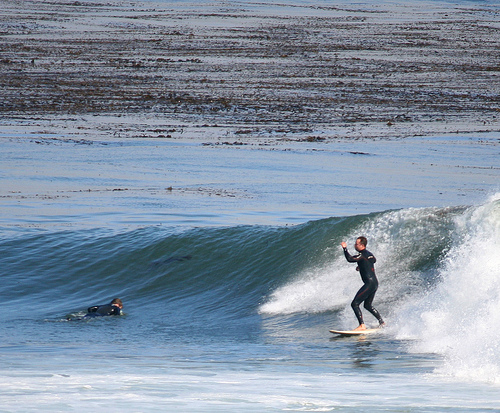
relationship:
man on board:
[341, 234, 388, 331] [304, 289, 422, 326]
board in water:
[328, 327, 380, 334] [0, 134, 499, 409]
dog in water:
[73, 297, 121, 321] [139, 136, 271, 384]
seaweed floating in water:
[3, 10, 497, 145] [0, 3, 497, 409]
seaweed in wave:
[144, 250, 194, 265] [7, 190, 498, 388]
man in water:
[341, 234, 388, 331] [0, 199, 481, 411]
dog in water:
[73, 297, 121, 319] [0, 3, 497, 409]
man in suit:
[341, 234, 388, 331] [342, 246, 384, 326]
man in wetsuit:
[79, 298, 124, 321] [87, 304, 122, 318]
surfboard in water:
[328, 327, 388, 337] [0, 3, 497, 409]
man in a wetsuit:
[323, 228, 395, 333] [351, 251, 380, 324]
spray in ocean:
[283, 210, 498, 386] [2, 1, 484, 411]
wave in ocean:
[9, 190, 495, 342] [2, 1, 484, 411]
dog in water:
[73, 297, 121, 321] [64, 117, 331, 355]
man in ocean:
[341, 234, 388, 331] [2, 1, 484, 411]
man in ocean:
[79, 298, 124, 321] [2, 1, 484, 411]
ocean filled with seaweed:
[2, 1, 484, 411] [0, 3, 496, 125]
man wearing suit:
[341, 232, 383, 325] [342, 246, 384, 326]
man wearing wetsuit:
[79, 298, 124, 321] [80, 302, 122, 317]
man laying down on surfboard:
[79, 298, 124, 321] [117, 306, 127, 316]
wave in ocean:
[9, 190, 495, 342] [46, 104, 349, 281]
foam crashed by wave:
[437, 236, 497, 383] [383, 199, 498, 331]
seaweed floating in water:
[144, 250, 194, 265] [140, 267, 225, 293]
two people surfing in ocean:
[36, 202, 411, 353] [2, 1, 484, 411]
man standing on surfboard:
[341, 234, 388, 331] [329, 326, 380, 339]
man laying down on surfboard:
[79, 298, 124, 321] [92, 309, 130, 318]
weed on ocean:
[71, 178, 233, 199] [2, 1, 484, 411]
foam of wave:
[437, 236, 497, 383] [0, 197, 497, 375]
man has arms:
[341, 234, 388, 331] [332, 238, 360, 264]